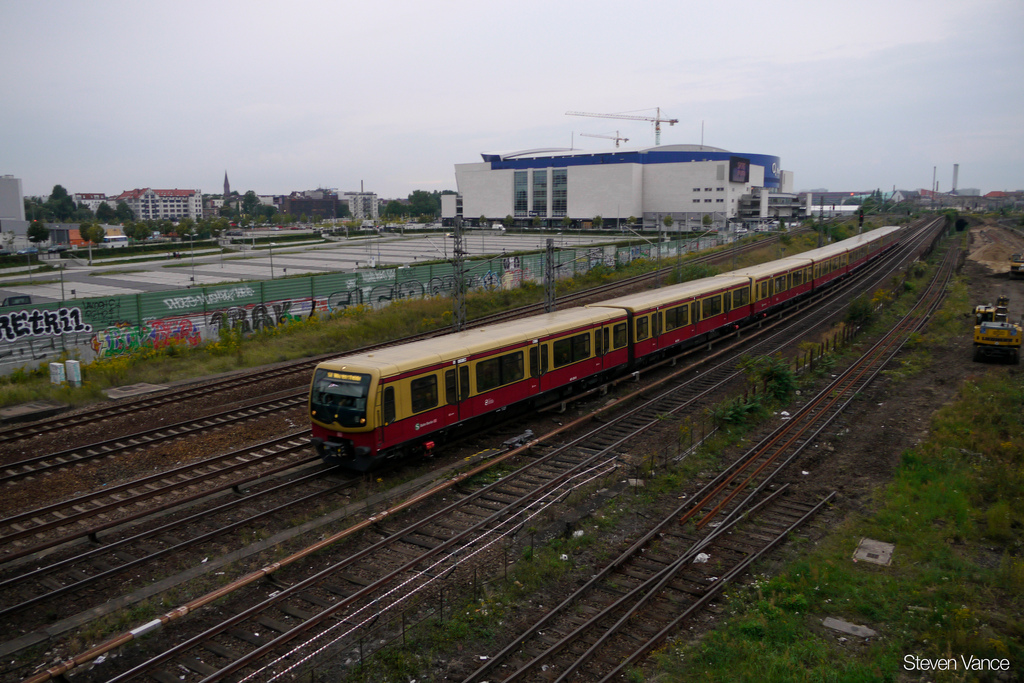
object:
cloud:
[0, 0, 1024, 190]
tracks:
[462, 340, 842, 680]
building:
[440, 143, 801, 231]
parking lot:
[0, 233, 655, 304]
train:
[310, 224, 902, 470]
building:
[117, 188, 166, 225]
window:
[310, 368, 371, 413]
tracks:
[50, 465, 828, 683]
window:
[410, 373, 440, 414]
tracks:
[2, 425, 316, 561]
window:
[474, 350, 525, 394]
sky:
[0, 0, 1015, 196]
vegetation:
[304, 212, 963, 682]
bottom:
[302, 438, 521, 474]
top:
[314, 222, 895, 380]